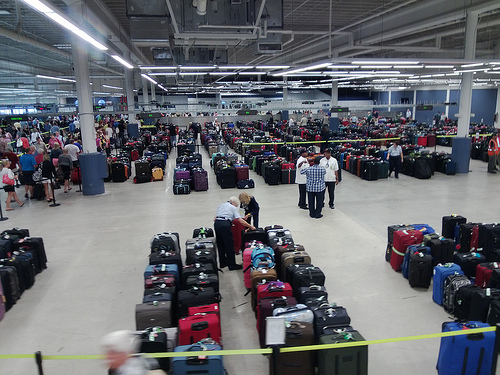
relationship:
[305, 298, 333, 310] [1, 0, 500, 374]
briefcase in airport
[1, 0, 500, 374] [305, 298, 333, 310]
airport with a briefcase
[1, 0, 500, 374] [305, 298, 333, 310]
airport with briefcase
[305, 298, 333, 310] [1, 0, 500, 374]
briefcase in big airport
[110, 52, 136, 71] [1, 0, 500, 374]
light above airport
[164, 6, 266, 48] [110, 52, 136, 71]
pipe by light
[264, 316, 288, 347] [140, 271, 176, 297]
sign by suitcase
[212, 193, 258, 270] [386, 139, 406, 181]
person and woman